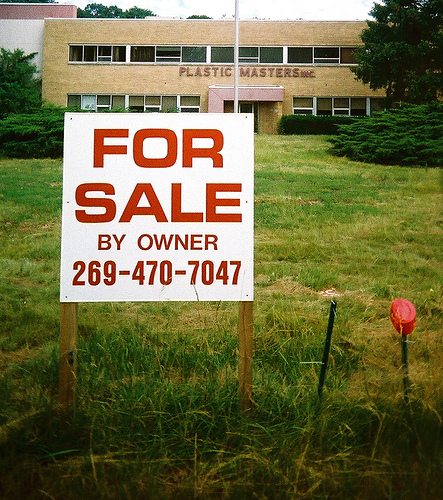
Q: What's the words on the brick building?
A: PLASTIC MASTERS INC.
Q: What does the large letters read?
A: For sale.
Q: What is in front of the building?
A: Flag pole.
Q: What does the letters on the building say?
A: Plastic masters inc.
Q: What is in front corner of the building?
A: Tree.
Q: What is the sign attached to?
A: Stakes.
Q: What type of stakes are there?
A: Wooden.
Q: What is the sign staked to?
A: Grass.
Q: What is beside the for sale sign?
A: Reflector.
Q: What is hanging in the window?
A: Curtains.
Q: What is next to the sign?
A: Green poles.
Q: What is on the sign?
A: A phone number and a for sale sign.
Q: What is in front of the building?
A: A flagpole.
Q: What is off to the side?
A: Trees.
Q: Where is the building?
A: Behind the sign.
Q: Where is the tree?
A: In the corner.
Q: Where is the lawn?
A: In front of the building?.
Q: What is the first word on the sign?
A: FOR.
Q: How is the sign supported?
A: Posts.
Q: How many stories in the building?
A: Two.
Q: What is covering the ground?
A: Green grass.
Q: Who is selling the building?
A: Owner.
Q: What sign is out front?
A: A "FOR SALE" sign.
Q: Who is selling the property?
A: The owner.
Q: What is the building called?
A: Plastic Masters, Inc.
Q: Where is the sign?
A: In front of the building.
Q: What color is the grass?
A: Green.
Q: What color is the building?
A: Brown.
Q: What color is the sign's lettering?
A: Red.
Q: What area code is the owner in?
A: 269.